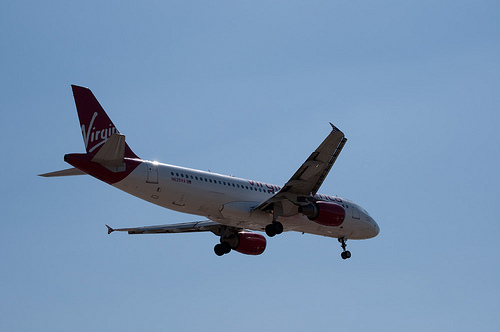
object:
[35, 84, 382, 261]
jet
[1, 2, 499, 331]
air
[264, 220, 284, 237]
wheels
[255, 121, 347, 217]
wing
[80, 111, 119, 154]
logo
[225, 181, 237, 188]
window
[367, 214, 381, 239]
nose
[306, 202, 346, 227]
engine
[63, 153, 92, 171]
tail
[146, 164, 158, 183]
door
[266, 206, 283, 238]
landing gear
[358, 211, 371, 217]
cockpit